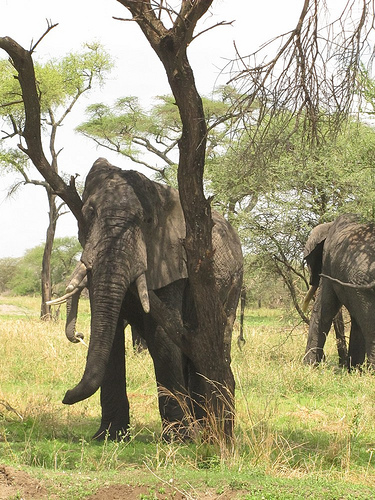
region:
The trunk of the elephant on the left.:
[68, 276, 106, 408]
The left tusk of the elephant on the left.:
[66, 266, 84, 287]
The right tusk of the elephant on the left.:
[137, 272, 152, 313]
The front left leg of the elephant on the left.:
[81, 293, 130, 444]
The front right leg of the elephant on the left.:
[128, 291, 194, 440]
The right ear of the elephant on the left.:
[143, 189, 187, 291]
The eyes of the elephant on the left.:
[80, 204, 156, 232]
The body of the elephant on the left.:
[162, 191, 239, 342]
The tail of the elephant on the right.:
[313, 258, 373, 295]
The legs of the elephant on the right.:
[310, 289, 374, 380]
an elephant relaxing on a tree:
[64, 157, 243, 440]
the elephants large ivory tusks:
[135, 272, 150, 312]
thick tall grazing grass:
[240, 287, 303, 498]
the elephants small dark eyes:
[145, 214, 154, 224]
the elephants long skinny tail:
[319, 273, 374, 288]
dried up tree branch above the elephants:
[232, 0, 337, 129]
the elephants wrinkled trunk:
[62, 241, 135, 408]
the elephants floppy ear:
[298, 221, 333, 259]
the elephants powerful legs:
[305, 280, 338, 364]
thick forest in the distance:
[0, 239, 73, 294]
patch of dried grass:
[302, 458, 335, 474]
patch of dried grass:
[201, 427, 239, 473]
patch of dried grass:
[137, 428, 173, 464]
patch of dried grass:
[87, 427, 126, 468]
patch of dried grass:
[297, 408, 321, 436]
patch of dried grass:
[264, 358, 283, 382]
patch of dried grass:
[326, 378, 344, 408]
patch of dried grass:
[30, 336, 56, 368]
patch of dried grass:
[243, 350, 258, 372]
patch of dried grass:
[340, 376, 372, 407]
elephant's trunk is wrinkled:
[86, 187, 127, 429]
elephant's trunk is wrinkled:
[49, 210, 162, 439]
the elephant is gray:
[27, 153, 241, 472]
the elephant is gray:
[289, 207, 371, 380]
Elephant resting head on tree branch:
[61, 155, 245, 444]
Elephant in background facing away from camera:
[301, 212, 373, 373]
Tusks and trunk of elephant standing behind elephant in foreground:
[45, 281, 84, 343]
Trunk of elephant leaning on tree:
[61, 281, 131, 404]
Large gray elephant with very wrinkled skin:
[61, 156, 244, 444]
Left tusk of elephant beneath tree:
[133, 270, 151, 314]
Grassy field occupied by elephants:
[2, 294, 373, 497]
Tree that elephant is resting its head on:
[2, 1, 239, 445]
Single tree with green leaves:
[1, 38, 116, 323]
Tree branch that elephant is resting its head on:
[0, 16, 196, 362]